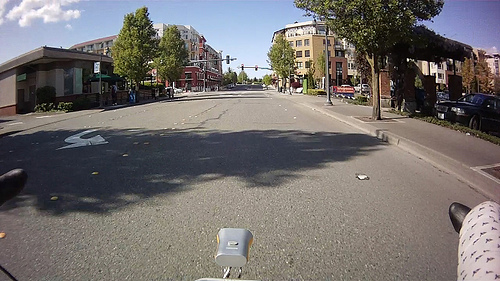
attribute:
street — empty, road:
[4, 90, 494, 277]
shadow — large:
[1, 131, 388, 212]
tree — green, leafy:
[112, 4, 162, 103]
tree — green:
[158, 23, 191, 87]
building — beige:
[284, 34, 337, 86]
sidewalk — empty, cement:
[287, 91, 499, 201]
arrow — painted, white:
[56, 126, 109, 151]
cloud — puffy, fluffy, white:
[0, 0, 84, 34]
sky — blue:
[2, 2, 499, 76]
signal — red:
[241, 62, 246, 71]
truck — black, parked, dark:
[436, 91, 500, 133]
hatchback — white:
[355, 82, 371, 95]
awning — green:
[94, 72, 112, 81]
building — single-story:
[0, 43, 131, 115]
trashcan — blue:
[129, 89, 138, 105]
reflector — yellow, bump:
[51, 195, 59, 202]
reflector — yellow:
[91, 168, 100, 177]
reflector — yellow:
[159, 132, 167, 138]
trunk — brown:
[366, 55, 383, 120]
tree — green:
[291, 0, 445, 119]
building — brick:
[162, 66, 223, 90]